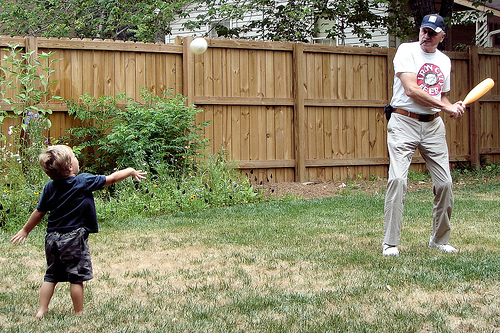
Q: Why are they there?
A: To play.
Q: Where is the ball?
A: In the air.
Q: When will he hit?
A: Soon.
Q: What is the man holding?
A: Bat.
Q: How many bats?
A: 1.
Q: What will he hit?
A: Ball.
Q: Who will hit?
A: The man.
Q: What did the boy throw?
A: Ball.